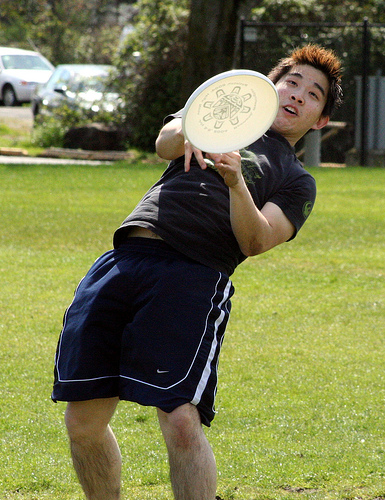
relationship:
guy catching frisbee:
[63, 43, 340, 498] [185, 68, 280, 158]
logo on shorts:
[155, 366, 170, 377] [53, 236, 236, 426]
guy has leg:
[63, 43, 340, 498] [160, 402, 218, 500]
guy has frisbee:
[63, 43, 340, 498] [185, 68, 280, 158]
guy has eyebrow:
[63, 43, 340, 498] [290, 70, 307, 82]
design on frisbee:
[195, 79, 260, 135] [185, 68, 280, 158]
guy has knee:
[63, 43, 340, 498] [64, 404, 107, 438]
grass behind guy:
[3, 162, 380, 498] [63, 43, 340, 498]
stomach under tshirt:
[119, 224, 166, 243] [111, 104, 319, 279]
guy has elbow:
[63, 43, 340, 498] [155, 133, 169, 165]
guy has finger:
[63, 43, 340, 498] [183, 147, 195, 169]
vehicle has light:
[1, 48, 57, 113] [19, 77, 34, 88]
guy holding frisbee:
[63, 43, 340, 498] [185, 68, 280, 158]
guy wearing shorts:
[63, 43, 340, 498] [53, 236, 236, 426]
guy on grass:
[63, 43, 340, 498] [3, 162, 380, 498]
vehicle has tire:
[1, 48, 57, 113] [1, 85, 16, 108]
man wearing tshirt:
[315, 81, 329, 98] [111, 104, 319, 279]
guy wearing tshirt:
[63, 43, 340, 498] [111, 104, 319, 279]